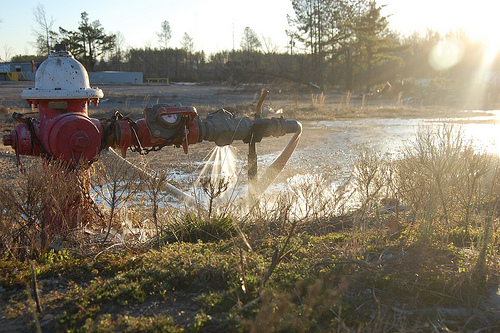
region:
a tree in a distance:
[236, 23, 265, 84]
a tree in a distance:
[29, 3, 61, 65]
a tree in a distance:
[60, 12, 82, 64]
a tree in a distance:
[77, 10, 112, 62]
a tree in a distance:
[178, 30, 200, 79]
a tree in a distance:
[289, 3, 333, 88]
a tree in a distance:
[356, 2, 389, 107]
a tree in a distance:
[207, 48, 226, 80]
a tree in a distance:
[129, 43, 144, 68]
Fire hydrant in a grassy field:
[8, 28, 230, 289]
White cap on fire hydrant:
[16, 32, 108, 120]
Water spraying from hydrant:
[164, 115, 322, 246]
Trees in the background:
[20, 1, 478, 102]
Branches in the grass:
[224, 191, 407, 323]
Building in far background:
[0, 56, 155, 103]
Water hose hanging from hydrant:
[19, 100, 336, 305]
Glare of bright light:
[362, 1, 499, 143]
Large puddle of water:
[69, 90, 499, 281]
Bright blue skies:
[1, 1, 306, 71]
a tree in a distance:
[2, 39, 19, 64]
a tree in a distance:
[76, 7, 95, 62]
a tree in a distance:
[91, 20, 124, 60]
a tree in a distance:
[156, 15, 175, 47]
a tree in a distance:
[176, 28, 201, 54]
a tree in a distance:
[318, 4, 364, 86]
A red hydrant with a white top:
[10, 40, 136, 255]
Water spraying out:
[190, 135, 250, 200]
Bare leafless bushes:
[390, 125, 485, 230]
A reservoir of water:
[310, 120, 410, 155]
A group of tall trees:
[285, 0, 385, 85]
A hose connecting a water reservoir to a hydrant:
[85, 135, 210, 205]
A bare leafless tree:
[25, 0, 55, 40]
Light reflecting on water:
[380, 115, 480, 150]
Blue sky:
[2, 6, 27, 31]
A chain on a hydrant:
[70, 171, 121, 229]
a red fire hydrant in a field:
[4, 42, 118, 327]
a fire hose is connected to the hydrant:
[123, 97, 305, 220]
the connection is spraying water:
[183, 113, 280, 233]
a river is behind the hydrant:
[6, 110, 498, 265]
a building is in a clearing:
[6, 56, 189, 103]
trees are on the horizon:
[4, 2, 492, 86]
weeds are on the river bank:
[8, 143, 499, 329]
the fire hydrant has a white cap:
[23, 45, 101, 100]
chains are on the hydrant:
[14, 152, 111, 239]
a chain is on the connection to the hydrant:
[115, 101, 197, 167]